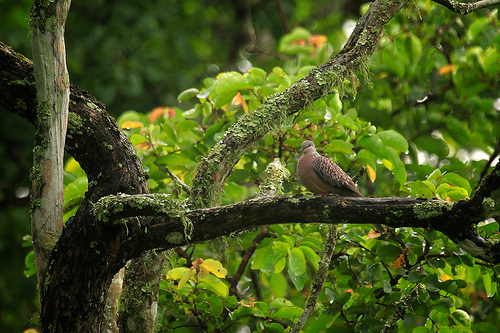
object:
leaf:
[268, 302, 305, 320]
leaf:
[377, 128, 409, 155]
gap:
[416, 148, 428, 165]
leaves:
[443, 118, 476, 153]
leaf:
[163, 266, 189, 280]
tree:
[0, 2, 498, 333]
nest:
[92, 192, 180, 221]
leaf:
[168, 271, 196, 289]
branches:
[281, 225, 347, 333]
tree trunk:
[28, 0, 73, 315]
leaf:
[370, 130, 409, 156]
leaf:
[314, 42, 334, 67]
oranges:
[121, 118, 145, 131]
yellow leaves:
[230, 93, 250, 116]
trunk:
[66, 86, 146, 200]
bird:
[291, 137, 370, 201]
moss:
[235, 98, 284, 136]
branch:
[192, 0, 406, 213]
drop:
[314, 103, 335, 127]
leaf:
[325, 139, 359, 157]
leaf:
[288, 247, 308, 276]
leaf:
[349, 148, 380, 183]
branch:
[170, 193, 463, 247]